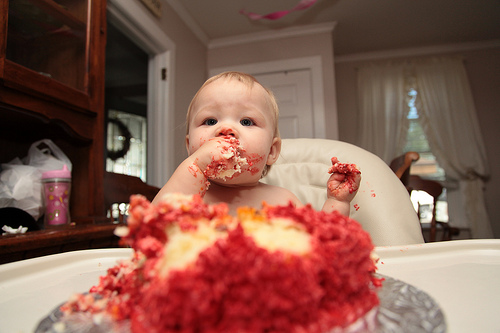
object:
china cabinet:
[0, 0, 105, 110]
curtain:
[356, 60, 411, 165]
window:
[399, 88, 448, 222]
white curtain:
[410, 57, 497, 239]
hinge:
[162, 67, 167, 81]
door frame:
[108, 0, 178, 189]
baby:
[128, 72, 359, 227]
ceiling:
[156, 0, 500, 56]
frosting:
[61, 193, 386, 331]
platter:
[35, 270, 447, 331]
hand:
[186, 141, 243, 181]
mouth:
[211, 149, 243, 168]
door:
[255, 70, 313, 139]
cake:
[60, 191, 384, 331]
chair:
[0, 136, 500, 332]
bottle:
[43, 162, 74, 232]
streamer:
[224, 0, 318, 28]